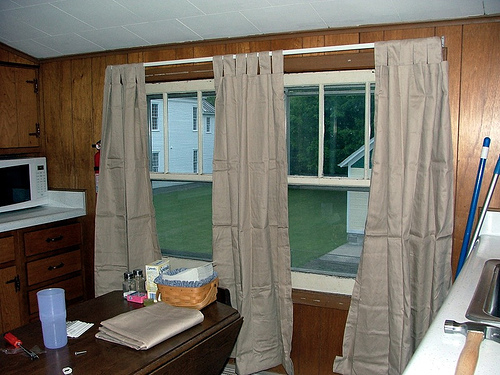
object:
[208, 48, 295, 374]
curtain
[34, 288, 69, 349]
cup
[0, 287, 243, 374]
table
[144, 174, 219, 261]
window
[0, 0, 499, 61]
ceiling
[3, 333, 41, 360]
screwdriver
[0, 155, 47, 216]
microwave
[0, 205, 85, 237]
counter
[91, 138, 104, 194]
extinguisher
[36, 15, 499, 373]
wall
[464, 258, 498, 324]
sink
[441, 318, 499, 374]
hammer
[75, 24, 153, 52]
tile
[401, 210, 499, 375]
counter